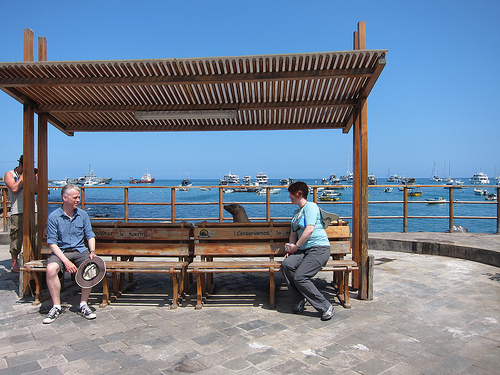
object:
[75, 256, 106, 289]
hat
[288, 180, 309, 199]
hair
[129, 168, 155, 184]
boat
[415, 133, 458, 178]
ground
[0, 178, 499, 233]
water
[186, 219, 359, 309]
bench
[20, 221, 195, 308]
bench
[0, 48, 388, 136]
awing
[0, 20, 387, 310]
structure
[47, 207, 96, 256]
blue shirt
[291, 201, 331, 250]
shirt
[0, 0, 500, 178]
sky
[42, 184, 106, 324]
man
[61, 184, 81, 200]
hair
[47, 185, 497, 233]
railing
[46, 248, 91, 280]
shorts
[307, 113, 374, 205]
wall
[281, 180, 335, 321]
strangers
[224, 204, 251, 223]
sea lion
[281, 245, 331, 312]
pants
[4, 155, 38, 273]
man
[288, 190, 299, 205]
skin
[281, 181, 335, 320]
person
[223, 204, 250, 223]
animal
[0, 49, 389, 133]
slats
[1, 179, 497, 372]
harbor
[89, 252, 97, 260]
hand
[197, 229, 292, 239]
rust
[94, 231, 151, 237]
rust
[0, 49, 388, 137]
awning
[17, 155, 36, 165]
hat